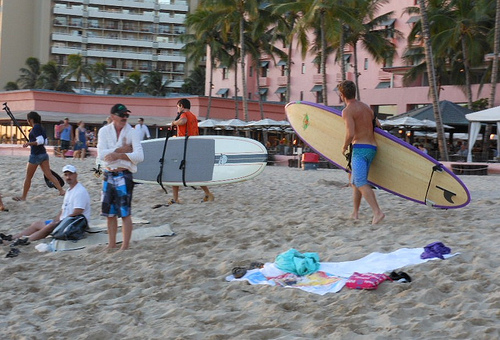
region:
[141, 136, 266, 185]
grey and white surf board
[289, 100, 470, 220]
tan and blue surfboard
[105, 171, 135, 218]
blue and white swim trunks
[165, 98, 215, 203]
man wearing red shirt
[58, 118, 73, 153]
man wearing blue shirt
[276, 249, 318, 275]
blue towel on ground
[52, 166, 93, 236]
man wearing white hat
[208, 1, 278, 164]
palm tree by beach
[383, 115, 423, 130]
white umbrella by beach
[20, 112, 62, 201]
girl walking on beach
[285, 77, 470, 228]
a man carrying a surfboard with purple.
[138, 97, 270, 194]
a man carrying a surfboard with gray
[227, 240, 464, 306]
some towels left on the sand alone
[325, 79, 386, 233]
the man with blue shorts has no shirt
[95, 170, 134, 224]
these swimming trunks are blue plaid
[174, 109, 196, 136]
this man has an orange shirt on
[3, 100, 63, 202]
this woman is carrying oars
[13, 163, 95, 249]
a man sitting in the sand with a backpack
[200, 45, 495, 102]
the building in the background is pink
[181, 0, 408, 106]
a few palm trees by the dining area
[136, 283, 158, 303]
part of a beach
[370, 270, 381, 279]
part of a towel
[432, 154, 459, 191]
part of a board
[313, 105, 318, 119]
tip of a board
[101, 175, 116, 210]
part of a short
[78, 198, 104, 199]
part of a shirt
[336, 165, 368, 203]
part of a short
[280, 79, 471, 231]
Man carrying surfboard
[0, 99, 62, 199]
Woman carrying oars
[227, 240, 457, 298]
Towel on beach with clothes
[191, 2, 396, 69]
Palm trees near a beach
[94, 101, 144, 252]
Man in sunglasses with black hat watching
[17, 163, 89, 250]
Man in white hat sitting down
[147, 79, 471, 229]
Two men carrying water sport devices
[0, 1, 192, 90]
Large building with windows near beach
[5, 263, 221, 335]
Sand on the beach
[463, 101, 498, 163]
White tent near the beach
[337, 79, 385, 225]
young man is shirtless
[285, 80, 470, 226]
shirtless young man carrying surfboard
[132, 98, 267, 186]
man carrying white and gray paddleboard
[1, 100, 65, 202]
young woman carrying paddle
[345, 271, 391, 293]
pink and purple totebag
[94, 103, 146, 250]
man in sunglasses and cap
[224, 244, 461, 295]
white towel on beach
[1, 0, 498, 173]
hotel is painted pink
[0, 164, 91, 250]
man has black backpack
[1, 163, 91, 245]
man wearing white cap